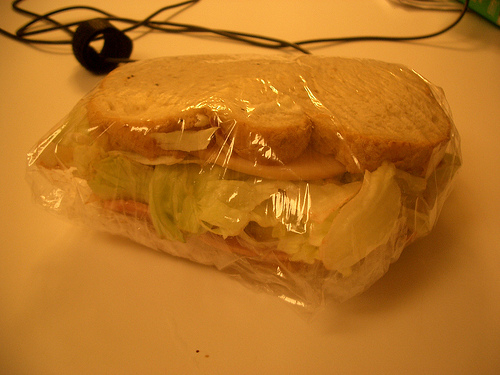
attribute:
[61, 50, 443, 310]
bread — curved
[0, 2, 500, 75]
cord — black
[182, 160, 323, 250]
lettuce — green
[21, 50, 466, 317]
wrap — plastic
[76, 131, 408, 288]
lettuce — green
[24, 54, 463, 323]
wrapping — curled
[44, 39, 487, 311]
sandwich — wrapped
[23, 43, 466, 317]
plastic — shiny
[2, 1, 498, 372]
surface — white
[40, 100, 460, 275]
lettuce — green